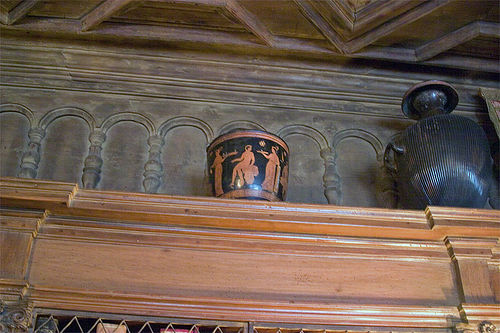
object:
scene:
[0, 0, 499, 332]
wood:
[0, 175, 499, 333]